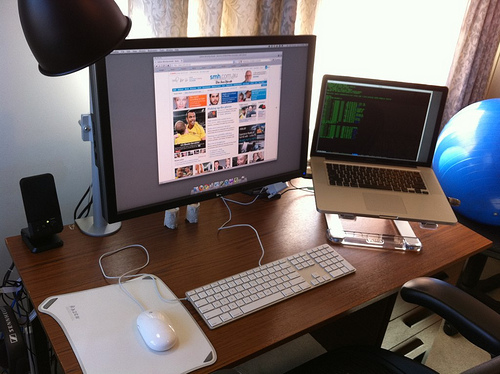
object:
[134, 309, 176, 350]
mouse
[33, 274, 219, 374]
mouse pad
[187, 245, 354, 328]
keyboard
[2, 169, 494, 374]
desk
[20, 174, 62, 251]
speaker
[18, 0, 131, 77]
lamp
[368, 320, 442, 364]
drawer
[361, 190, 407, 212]
mouse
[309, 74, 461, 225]
laptop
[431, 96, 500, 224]
ball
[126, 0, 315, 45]
curtains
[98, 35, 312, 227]
monitor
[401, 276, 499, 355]
arm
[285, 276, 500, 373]
chair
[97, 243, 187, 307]
wire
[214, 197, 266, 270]
wire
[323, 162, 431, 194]
keyboard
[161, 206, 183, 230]
support